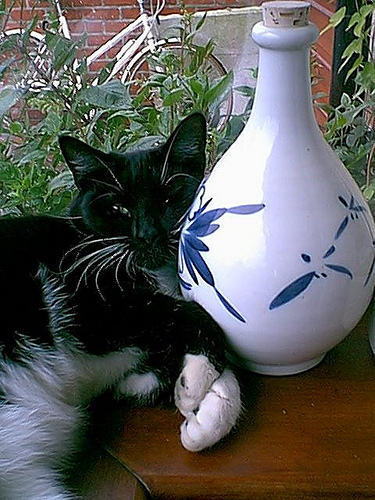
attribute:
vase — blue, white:
[233, 49, 309, 260]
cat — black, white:
[0, 112, 248, 499]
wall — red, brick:
[3, 1, 329, 170]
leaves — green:
[115, 55, 235, 125]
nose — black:
[134, 224, 162, 241]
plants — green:
[1, 0, 236, 217]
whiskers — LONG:
[59, 235, 134, 296]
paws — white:
[139, 337, 233, 458]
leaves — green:
[165, 60, 218, 105]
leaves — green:
[8, 33, 118, 112]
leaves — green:
[5, 166, 46, 207]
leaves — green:
[321, 5, 366, 67]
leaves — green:
[341, 120, 362, 157]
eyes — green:
[107, 198, 174, 212]